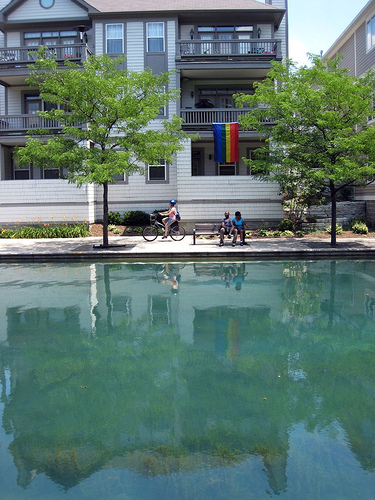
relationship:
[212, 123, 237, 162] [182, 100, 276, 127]
rainbow flag hanging off deck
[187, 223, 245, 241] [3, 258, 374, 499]
bench beside a pool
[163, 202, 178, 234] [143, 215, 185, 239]
person riding bicycle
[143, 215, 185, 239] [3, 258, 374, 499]
bicycle next to pool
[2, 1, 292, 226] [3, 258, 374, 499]
building next to pool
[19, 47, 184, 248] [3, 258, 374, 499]
tree next to pool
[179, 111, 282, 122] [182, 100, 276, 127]
wooden railing on deck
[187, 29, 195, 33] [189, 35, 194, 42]
light on top of a pole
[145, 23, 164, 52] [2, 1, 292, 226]
window on building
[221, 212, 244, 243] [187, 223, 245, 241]
two people sitting on a bench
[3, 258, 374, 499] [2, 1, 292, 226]
pool in front of building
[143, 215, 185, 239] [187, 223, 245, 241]
bicycle next to bench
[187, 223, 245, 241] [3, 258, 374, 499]
bench in front of pool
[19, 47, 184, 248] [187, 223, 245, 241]
tree next to bench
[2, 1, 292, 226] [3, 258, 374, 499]
building behind pool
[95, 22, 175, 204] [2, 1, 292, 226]
wall on building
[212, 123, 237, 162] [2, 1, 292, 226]
rainbow flag hanging from building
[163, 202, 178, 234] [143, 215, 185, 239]
person riding on a bicycle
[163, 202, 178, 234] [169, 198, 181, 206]
person wearing helmet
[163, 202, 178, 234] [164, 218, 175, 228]
person wearing shorts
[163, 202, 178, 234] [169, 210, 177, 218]
person wearing pink shirt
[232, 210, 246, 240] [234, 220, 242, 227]
person wearing blue shirt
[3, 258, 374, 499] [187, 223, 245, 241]
water in front of bench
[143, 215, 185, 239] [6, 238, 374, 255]
bicycle on sidewalk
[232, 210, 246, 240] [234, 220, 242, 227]
woman wearing blue shirt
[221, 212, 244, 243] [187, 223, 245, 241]
man and woman sitting on bench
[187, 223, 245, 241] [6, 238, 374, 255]
bench on sidewalk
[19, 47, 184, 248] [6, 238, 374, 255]
tree on sidewalk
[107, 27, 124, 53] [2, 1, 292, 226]
window on building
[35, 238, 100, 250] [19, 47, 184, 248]
shadow from tree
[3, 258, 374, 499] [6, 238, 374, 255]
swimming pool in front of sidewalk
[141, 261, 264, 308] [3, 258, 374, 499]
reflections in swimming pool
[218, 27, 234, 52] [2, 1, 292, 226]
door on building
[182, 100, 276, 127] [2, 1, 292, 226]
balcony on building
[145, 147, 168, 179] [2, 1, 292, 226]
window on building